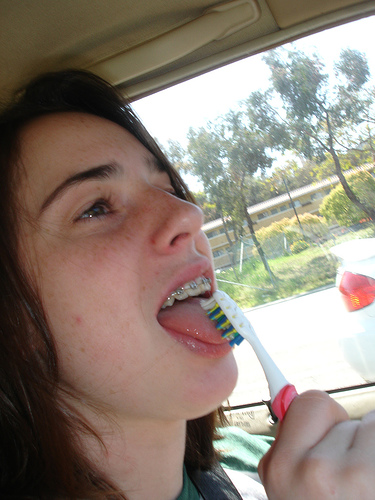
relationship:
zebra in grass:
[1, 0, 3, 3] [212, 219, 370, 320]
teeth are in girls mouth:
[161, 271, 213, 310] [153, 261, 238, 353]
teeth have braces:
[161, 271, 213, 310] [162, 276, 212, 302]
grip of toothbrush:
[263, 385, 302, 419] [199, 289, 302, 418]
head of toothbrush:
[201, 290, 254, 348] [199, 289, 302, 418]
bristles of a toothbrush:
[199, 296, 243, 345] [199, 289, 302, 418]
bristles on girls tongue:
[199, 296, 243, 345] [159, 296, 226, 343]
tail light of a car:
[341, 271, 373, 313] [327, 239, 374, 381]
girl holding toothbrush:
[3, 82, 369, 497] [199, 289, 302, 418]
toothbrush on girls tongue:
[199, 289, 302, 418] [159, 296, 226, 343]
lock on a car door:
[262, 395, 280, 424] [107, 20, 374, 444]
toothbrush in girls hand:
[199, 289, 302, 418] [257, 389, 373, 499]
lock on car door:
[262, 395, 280, 424] [107, 20, 374, 444]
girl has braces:
[3, 82, 369, 497] [162, 276, 212, 302]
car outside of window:
[327, 239, 374, 381] [121, 15, 373, 402]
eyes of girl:
[65, 188, 191, 221] [3, 82, 369, 497]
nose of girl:
[138, 186, 204, 255] [3, 82, 369, 497]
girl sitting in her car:
[3, 82, 369, 497] [1, 1, 374, 500]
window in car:
[121, 15, 373, 402] [1, 1, 374, 500]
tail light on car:
[341, 271, 373, 313] [327, 239, 374, 381]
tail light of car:
[341, 271, 373, 313] [327, 239, 374, 381]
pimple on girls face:
[72, 314, 83, 325] [13, 117, 238, 418]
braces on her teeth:
[162, 276, 212, 302] [161, 271, 213, 310]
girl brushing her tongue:
[3, 82, 369, 497] [159, 296, 226, 343]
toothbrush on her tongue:
[199, 289, 302, 418] [159, 296, 226, 343]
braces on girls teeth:
[162, 276, 212, 302] [161, 271, 213, 310]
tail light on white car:
[341, 271, 373, 313] [327, 239, 374, 381]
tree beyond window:
[189, 122, 281, 293] [121, 15, 373, 402]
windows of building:
[204, 186, 329, 247] [208, 162, 371, 277]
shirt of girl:
[175, 427, 276, 500] [3, 82, 369, 497]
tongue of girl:
[159, 296, 226, 343] [3, 82, 369, 497]